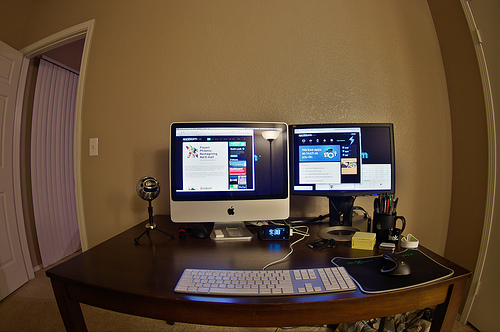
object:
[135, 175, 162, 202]
webcam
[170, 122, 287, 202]
computer monitor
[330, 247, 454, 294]
park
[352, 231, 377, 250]
stack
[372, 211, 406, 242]
cup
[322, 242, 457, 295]
mouse pad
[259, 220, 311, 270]
cord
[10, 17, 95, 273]
doorway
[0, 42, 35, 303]
door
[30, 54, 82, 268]
blinds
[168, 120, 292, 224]
monitor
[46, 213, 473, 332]
desk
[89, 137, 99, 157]
switch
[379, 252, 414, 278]
computer mouse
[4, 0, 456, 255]
wall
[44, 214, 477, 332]
wooden desk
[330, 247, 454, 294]
mousepad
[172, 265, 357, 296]
keyboard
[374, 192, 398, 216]
pen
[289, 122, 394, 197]
monitor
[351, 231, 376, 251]
yellow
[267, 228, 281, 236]
usb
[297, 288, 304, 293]
key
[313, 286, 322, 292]
key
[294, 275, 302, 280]
key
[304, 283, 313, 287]
key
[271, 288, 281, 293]
key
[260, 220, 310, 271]
cable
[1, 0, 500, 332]
concrete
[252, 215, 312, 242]
charger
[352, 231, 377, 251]
sticky notes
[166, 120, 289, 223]
screen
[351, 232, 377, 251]
notes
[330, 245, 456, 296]
trim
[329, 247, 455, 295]
border